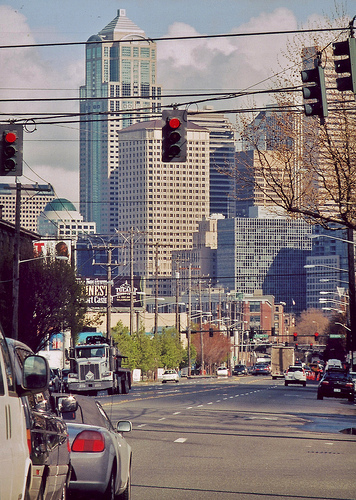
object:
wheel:
[121, 375, 129, 395]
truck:
[68, 335, 132, 397]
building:
[78, 8, 161, 274]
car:
[3, 336, 72, 500]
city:
[0, 10, 355, 498]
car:
[161, 369, 179, 383]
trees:
[134, 319, 156, 382]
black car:
[316, 368, 353, 400]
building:
[216, 216, 312, 314]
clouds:
[0, 5, 304, 170]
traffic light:
[315, 333, 320, 342]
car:
[234, 365, 245, 376]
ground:
[82, 372, 356, 500]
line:
[173, 437, 187, 444]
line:
[100, 376, 272, 407]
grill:
[80, 363, 100, 380]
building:
[116, 119, 210, 297]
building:
[162, 104, 234, 273]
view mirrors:
[20, 355, 47, 390]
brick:
[261, 305, 271, 327]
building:
[0, 182, 58, 241]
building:
[173, 216, 218, 290]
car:
[53, 395, 134, 500]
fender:
[68, 381, 113, 392]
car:
[285, 366, 306, 387]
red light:
[5, 133, 16, 143]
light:
[161, 108, 187, 162]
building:
[37, 198, 96, 237]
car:
[256, 365, 268, 376]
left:
[0, 0, 25, 500]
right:
[320, 0, 355, 500]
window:
[77, 347, 105, 357]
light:
[72, 430, 105, 453]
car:
[0, 332, 33, 500]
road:
[67, 378, 355, 500]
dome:
[44, 198, 77, 211]